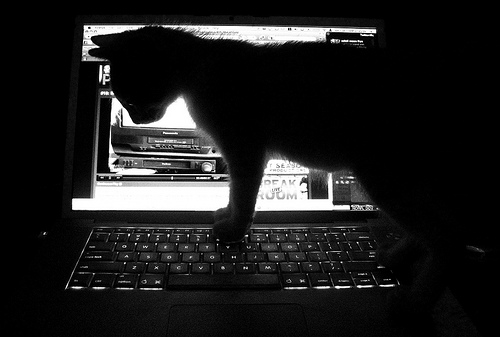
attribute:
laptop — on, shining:
[46, 16, 424, 330]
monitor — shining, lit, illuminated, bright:
[64, 10, 398, 223]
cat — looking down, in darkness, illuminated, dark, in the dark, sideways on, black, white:
[87, 19, 497, 268]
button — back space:
[345, 246, 387, 264]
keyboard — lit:
[64, 220, 404, 300]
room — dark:
[2, 2, 500, 335]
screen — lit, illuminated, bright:
[67, 14, 393, 223]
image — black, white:
[3, 2, 498, 336]